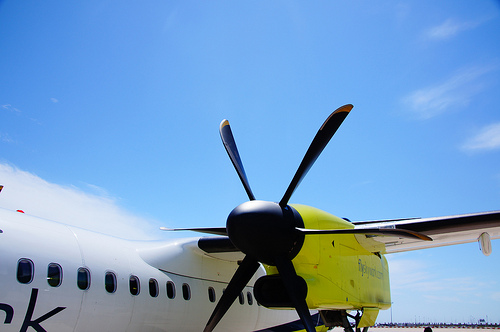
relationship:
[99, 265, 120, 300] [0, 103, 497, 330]
window on plane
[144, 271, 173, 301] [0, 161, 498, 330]
window on plane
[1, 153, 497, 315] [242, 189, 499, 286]
plane has wing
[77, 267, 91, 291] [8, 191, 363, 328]
window on plane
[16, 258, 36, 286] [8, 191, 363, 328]
window on plane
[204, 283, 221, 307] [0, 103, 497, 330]
window on plane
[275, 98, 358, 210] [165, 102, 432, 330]
blade on propellor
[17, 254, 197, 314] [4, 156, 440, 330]
windows on plane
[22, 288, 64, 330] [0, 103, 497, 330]
letter on plane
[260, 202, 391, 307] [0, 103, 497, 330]
part of plane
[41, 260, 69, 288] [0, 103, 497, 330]
window on plane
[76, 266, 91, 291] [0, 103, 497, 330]
window on plane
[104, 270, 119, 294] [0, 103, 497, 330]
window on plane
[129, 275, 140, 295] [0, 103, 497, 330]
window on plane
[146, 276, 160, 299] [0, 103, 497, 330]
window on plane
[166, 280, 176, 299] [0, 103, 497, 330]
window on plane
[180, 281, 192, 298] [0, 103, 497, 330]
window on plane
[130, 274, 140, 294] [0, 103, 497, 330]
window on plane